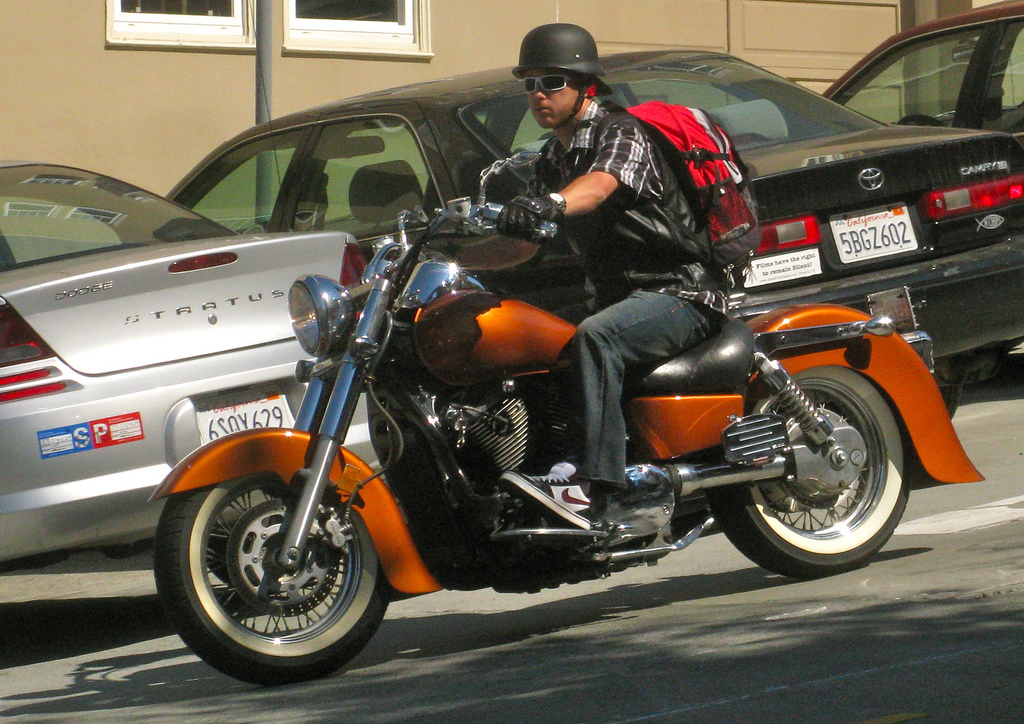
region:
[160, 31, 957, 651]
man riding a motorcycle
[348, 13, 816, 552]
Man wearing a black helmet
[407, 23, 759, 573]
Man wearing dark jeans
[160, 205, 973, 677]
Orange motorcycle going down street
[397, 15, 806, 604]
Man wearing dark gloves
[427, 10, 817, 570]
Man wearing a wrist watch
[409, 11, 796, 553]
Man wearing dark sneakers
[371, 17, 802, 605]
Man wearing a red backpack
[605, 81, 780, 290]
Red backpack on the man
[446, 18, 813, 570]
Man wearing black gloves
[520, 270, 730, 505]
Man wearing pants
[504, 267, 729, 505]
Man is wearing pants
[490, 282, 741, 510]
Man wearing blue pants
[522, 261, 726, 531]
Man is wearing blue pants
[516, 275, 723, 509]
Man wearing jeans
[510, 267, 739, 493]
Man is wearing jeans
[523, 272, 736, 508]
Man wearing blue jeans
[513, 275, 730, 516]
Man is wearing blue jeans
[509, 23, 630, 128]
Man is wearing a black helmet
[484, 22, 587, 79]
man has black helmet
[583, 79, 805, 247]
red and grey bag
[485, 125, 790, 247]
black and white shirt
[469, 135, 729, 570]
man has dark blue pants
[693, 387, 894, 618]
black tire on bike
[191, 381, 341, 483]
black and red license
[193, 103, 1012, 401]
black car behind man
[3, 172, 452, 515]
silver car behind man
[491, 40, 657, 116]
the head of a man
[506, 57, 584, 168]
the nose of a man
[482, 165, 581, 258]
the hand of a man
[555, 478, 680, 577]
the foot of a man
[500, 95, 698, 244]
the arm of a man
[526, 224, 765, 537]
the leg of a man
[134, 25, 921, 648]
a man on a bike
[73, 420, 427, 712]
the wheel of a bike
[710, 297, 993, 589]
the back wheel of a bike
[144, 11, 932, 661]
a man riding a motorcycle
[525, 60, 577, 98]
a man wearing sunglasses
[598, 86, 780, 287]
a man with red back pack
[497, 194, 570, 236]
a man wearing gloves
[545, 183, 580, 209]
a man wearing a wrist watch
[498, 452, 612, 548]
a man wearing a shoe with a logo on it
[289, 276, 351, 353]
a headlight on a motorcycle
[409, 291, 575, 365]
a gas tank on a motorcycle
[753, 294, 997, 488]
a rear fender on a motorcycle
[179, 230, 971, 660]
an orange motorcycle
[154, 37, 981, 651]
a man riding a motorcycle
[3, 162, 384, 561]
a parked silver car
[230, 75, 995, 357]
a parked black car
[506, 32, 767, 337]
a man wearing a red backpack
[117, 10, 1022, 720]
man riding motorcycle on street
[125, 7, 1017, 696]
man riding motorcycle on roadway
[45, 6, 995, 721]
man riding motorcycle behind parked cars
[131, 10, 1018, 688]
man riding motorcycle wearing backback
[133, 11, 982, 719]
man riding orange motorcycle on street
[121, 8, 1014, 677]
man on road riding orange motorcycle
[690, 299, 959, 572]
rear wheel of orange motorcycle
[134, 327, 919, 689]
front and rear wheels of orange motorcycle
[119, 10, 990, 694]
man riding motorcycle on street wearing black helmet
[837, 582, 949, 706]
shadow on the ground